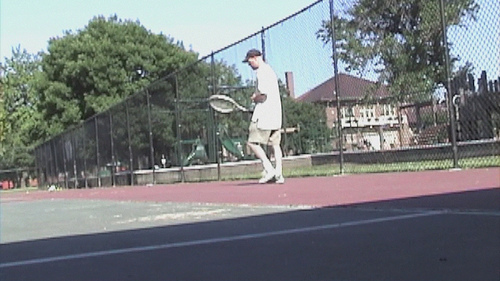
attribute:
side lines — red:
[74, 186, 457, 209]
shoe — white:
[275, 175, 283, 182]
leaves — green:
[3, 3, 498, 180]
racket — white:
[204, 85, 274, 122]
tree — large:
[313, 1, 498, 181]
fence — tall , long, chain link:
[29, 40, 496, 179]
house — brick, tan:
[290, 70, 416, 155]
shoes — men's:
[255, 166, 287, 186]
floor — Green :
[21, 183, 323, 265]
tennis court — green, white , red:
[0, 159, 500, 279]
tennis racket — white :
[206, 92, 255, 116]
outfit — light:
[245, 71, 286, 163]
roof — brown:
[295, 55, 408, 106]